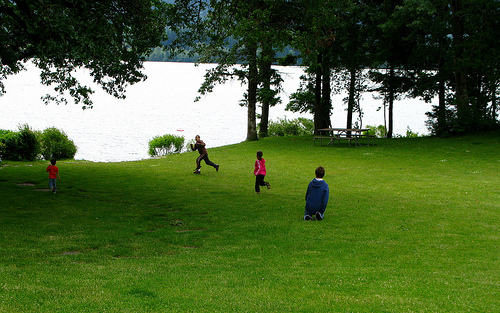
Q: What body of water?
A: Lake.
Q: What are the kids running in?
A: Grass.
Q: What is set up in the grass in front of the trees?
A: Picnic table.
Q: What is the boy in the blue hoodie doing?
A: Kneeling down.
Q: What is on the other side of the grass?
A: Water.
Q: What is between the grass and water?
A: Trees.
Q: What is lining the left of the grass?
A: Bushes.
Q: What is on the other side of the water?
A: Trees.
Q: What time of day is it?
A: Afternoon.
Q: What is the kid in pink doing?
A: Running.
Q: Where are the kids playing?
A: In the grass.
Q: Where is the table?
A: In the grass near the trees.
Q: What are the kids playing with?
A: A frisbee.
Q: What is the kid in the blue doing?
A: Sitting on his knees.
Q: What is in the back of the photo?
A: A lake.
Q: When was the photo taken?
A: Day time.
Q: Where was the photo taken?
A: In a park.